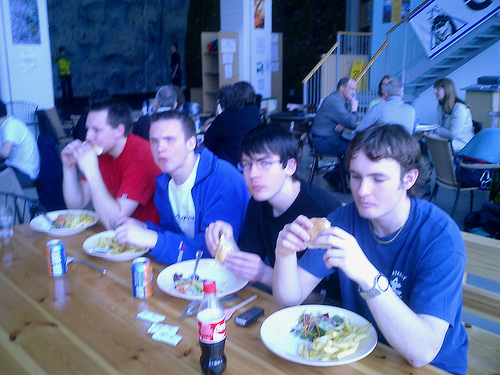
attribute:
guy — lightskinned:
[61, 101, 159, 230]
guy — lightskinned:
[147, 110, 245, 267]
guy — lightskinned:
[233, 121, 333, 303]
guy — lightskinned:
[329, 123, 467, 374]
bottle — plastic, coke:
[196, 279, 228, 373]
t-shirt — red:
[82, 135, 162, 225]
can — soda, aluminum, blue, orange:
[42, 238, 71, 279]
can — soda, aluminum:
[129, 256, 154, 300]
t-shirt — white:
[166, 177, 205, 238]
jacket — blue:
[153, 170, 248, 251]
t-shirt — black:
[247, 193, 339, 296]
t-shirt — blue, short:
[327, 199, 465, 373]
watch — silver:
[357, 274, 388, 301]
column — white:
[219, 0, 271, 120]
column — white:
[1, 1, 55, 122]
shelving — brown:
[200, 29, 236, 115]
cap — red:
[202, 280, 220, 293]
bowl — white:
[29, 208, 102, 236]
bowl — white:
[82, 230, 153, 259]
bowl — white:
[156, 258, 252, 299]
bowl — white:
[259, 302, 381, 367]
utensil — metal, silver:
[193, 248, 202, 284]